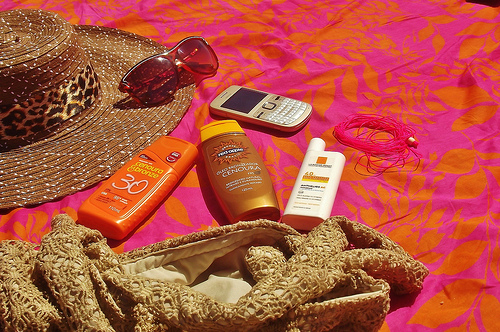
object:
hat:
[0, 9, 195, 210]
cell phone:
[209, 84, 314, 131]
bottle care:
[283, 138, 347, 231]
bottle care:
[200, 120, 282, 225]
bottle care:
[78, 135, 199, 241]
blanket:
[2, 1, 497, 330]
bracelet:
[333, 113, 424, 174]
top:
[201, 120, 248, 142]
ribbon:
[0, 65, 100, 151]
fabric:
[1, 213, 429, 330]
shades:
[115, 36, 216, 108]